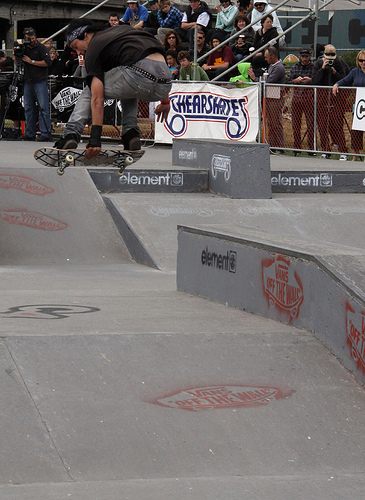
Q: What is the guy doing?
A: Skateboarding.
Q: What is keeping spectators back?
A: Fence.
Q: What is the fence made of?
A: Metal.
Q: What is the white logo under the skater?
A: Element.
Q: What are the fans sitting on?
A: Bleachers.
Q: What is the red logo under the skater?
A: Vans.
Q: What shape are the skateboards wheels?
A: Circle.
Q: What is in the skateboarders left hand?
A: Skateboard.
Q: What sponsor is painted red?
A: Vans.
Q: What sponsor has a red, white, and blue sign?
A: Cheapskates.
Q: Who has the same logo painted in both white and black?
A: Element.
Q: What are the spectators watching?
A: Skateboarding.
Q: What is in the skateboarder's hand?
A: Skateboard.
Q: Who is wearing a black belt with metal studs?
A: The skateboarder.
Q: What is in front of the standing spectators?
A: Fence.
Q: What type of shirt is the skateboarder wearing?
A: T-shirt.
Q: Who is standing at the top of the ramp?
A: Camera man.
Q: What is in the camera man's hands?
A: Camera.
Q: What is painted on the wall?
A: Corporate logos.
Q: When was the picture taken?
A: Daytime.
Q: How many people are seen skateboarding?
A: One.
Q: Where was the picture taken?
A: At a skatepark.